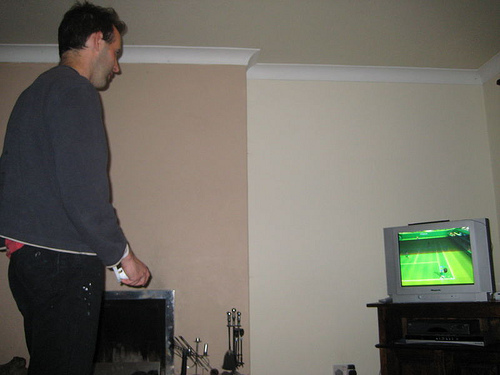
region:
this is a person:
[8, 0, 159, 371]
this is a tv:
[385, 211, 497, 306]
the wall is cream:
[392, 118, 462, 173]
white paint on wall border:
[317, 62, 406, 92]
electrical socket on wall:
[312, 353, 361, 373]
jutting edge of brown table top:
[356, 296, 384, 314]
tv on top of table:
[366, 198, 492, 303]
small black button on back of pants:
[31, 247, 43, 258]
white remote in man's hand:
[106, 239, 156, 296]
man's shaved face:
[86, 52, 125, 83]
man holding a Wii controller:
[101, 251, 163, 288]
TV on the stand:
[369, 203, 497, 303]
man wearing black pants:
[6, 244, 98, 374]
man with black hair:
[44, 0, 127, 80]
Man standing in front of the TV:
[6, 3, 171, 372]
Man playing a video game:
[6, 0, 176, 362]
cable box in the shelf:
[399, 315, 472, 342]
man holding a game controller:
[108, 249, 180, 310]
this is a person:
[1, 2, 157, 374]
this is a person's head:
[47, 0, 124, 90]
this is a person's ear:
[86, 28, 108, 50]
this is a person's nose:
[111, 57, 122, 74]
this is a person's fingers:
[121, 268, 162, 288]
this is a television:
[379, 216, 499, 313]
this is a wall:
[127, 60, 242, 373]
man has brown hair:
[31, 0, 158, 48]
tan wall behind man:
[145, 101, 222, 204]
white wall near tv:
[305, 120, 372, 177]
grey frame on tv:
[372, 187, 494, 282]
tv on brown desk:
[380, 287, 497, 359]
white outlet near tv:
[318, 355, 343, 371]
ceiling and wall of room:
[1, 0, 498, 373]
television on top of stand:
[366, 218, 498, 373]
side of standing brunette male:
[0, 3, 148, 373]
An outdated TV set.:
[373, 216, 497, 308]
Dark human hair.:
[59, 1, 129, 53]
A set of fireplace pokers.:
[219, 303, 246, 373]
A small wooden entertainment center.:
[365, 295, 498, 373]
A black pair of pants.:
[6, 240, 106, 372]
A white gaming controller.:
[110, 258, 137, 287]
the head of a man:
[50, 1, 138, 111]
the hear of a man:
[81, 23, 106, 54]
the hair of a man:
[60, 3, 108, 37]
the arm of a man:
[60, 85, 140, 277]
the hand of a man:
[112, 253, 152, 288]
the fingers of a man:
[130, 271, 157, 291]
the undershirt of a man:
[2, 228, 23, 262]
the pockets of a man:
[18, 259, 59, 320]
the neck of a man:
[58, 36, 88, 83]